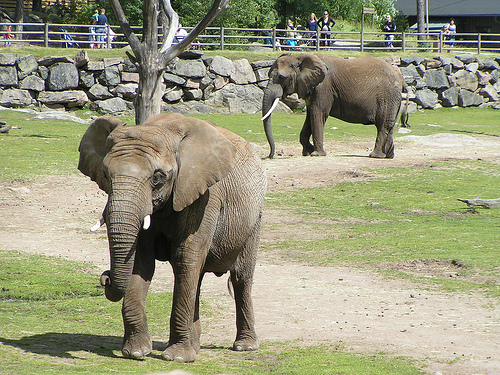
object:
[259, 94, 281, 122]
tusk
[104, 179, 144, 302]
trunk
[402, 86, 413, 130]
tail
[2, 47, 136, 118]
rocks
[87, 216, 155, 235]
tusks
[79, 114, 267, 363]
elephant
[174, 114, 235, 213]
ear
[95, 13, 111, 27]
shirt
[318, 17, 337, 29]
shirt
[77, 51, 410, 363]
elephants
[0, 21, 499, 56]
fence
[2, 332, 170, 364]
shadow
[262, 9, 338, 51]
people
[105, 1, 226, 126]
tree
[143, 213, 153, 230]
horn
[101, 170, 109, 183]
eye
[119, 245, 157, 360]
leg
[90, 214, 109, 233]
tusk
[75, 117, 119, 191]
ear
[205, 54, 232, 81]
stone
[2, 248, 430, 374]
grass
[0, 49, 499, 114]
wall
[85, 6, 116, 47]
spectators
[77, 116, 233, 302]
head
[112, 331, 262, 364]
feet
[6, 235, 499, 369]
sand